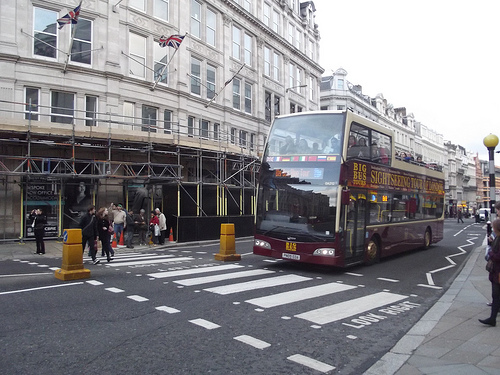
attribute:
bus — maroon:
[246, 90, 473, 281]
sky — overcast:
[378, 7, 443, 64]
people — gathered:
[63, 165, 183, 305]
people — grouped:
[74, 204, 172, 261]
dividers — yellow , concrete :
[36, 187, 268, 327]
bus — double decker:
[251, 101, 454, 278]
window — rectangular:
[34, 3, 60, 59]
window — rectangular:
[48, 88, 76, 125]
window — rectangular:
[126, 29, 146, 75]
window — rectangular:
[195, 120, 212, 136]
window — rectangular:
[204, 10, 219, 46]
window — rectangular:
[244, 83, 253, 108]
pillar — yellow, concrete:
[48, 224, 91, 281]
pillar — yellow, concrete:
[209, 217, 242, 261]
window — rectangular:
[4, 62, 139, 175]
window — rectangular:
[30, 5, 59, 58]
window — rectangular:
[21, 81, 42, 124]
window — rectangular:
[119, 20, 151, 85]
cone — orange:
[117, 230, 127, 246]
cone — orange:
[109, 227, 119, 250]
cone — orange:
[167, 227, 177, 243]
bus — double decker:
[265, 109, 455, 259]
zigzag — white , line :
[413, 223, 487, 300]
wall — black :
[177, 215, 252, 237]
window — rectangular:
[30, 83, 117, 130]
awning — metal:
[38, 122, 220, 185]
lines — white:
[96, 231, 403, 351]